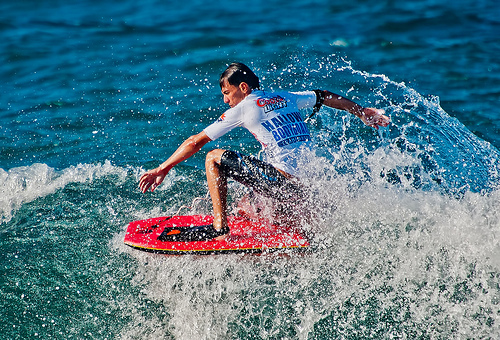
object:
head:
[219, 62, 261, 108]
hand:
[361, 108, 391, 130]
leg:
[202, 148, 291, 224]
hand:
[138, 169, 167, 194]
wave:
[290, 259, 483, 336]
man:
[137, 62, 389, 241]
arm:
[277, 87, 360, 114]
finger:
[139, 172, 149, 180]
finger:
[151, 176, 163, 192]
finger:
[142, 182, 153, 194]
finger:
[138, 176, 147, 187]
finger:
[367, 124, 380, 130]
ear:
[238, 82, 250, 94]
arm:
[160, 103, 242, 173]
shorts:
[220, 150, 306, 202]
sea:
[1, 0, 496, 340]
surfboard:
[124, 214, 315, 255]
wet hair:
[219, 62, 261, 92]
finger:
[375, 122, 388, 127]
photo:
[0, 0, 498, 338]